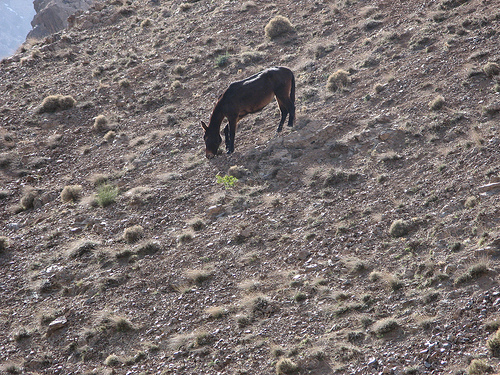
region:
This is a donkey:
[179, 50, 321, 194]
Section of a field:
[140, 240, 463, 373]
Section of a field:
[215, 232, 371, 372]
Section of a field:
[42, 195, 188, 371]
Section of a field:
[352, 82, 477, 260]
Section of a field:
[35, 58, 130, 221]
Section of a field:
[342, 25, 474, 180]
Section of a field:
[20, 25, 160, 205]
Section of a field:
[22, 180, 210, 370]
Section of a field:
[238, 217, 423, 373]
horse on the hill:
[201, 64, 354, 169]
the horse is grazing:
[193, 109, 266, 164]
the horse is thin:
[234, 82, 277, 117]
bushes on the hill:
[365, 300, 395, 356]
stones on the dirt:
[235, 335, 266, 356]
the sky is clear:
[1, 18, 27, 38]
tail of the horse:
[277, 70, 302, 125]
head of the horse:
[205, 123, 221, 158]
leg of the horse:
[270, 95, 288, 133]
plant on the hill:
[211, 173, 236, 192]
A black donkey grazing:
[177, 50, 305, 157]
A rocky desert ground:
[322, 271, 439, 369]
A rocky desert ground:
[74, 289, 258, 372]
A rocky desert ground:
[397, 88, 497, 291]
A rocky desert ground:
[168, 182, 365, 227]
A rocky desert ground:
[5, 41, 94, 170]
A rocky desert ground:
[52, 1, 212, 113]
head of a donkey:
[183, 116, 225, 159]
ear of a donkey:
[192, 112, 214, 134]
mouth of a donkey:
[205, 149, 215, 161]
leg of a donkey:
[225, 119, 239, 151]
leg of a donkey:
[265, 95, 287, 136]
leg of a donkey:
[283, 90, 297, 125]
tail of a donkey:
[289, 66, 309, 110]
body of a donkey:
[230, 73, 298, 103]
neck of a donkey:
[200, 108, 227, 128]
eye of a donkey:
[196, 132, 208, 142]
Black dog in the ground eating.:
[258, 205, 270, 225]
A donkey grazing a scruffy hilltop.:
[196, 65, 309, 163]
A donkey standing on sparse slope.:
[143, 45, 328, 179]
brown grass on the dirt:
[239, 297, 254, 307]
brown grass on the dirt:
[367, 310, 398, 337]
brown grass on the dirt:
[269, 354, 291, 373]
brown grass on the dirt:
[295, 346, 332, 365]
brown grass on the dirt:
[482, 333, 498, 352]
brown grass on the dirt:
[437, 268, 497, 298]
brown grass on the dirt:
[382, 215, 409, 240]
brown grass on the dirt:
[105, 304, 142, 342]